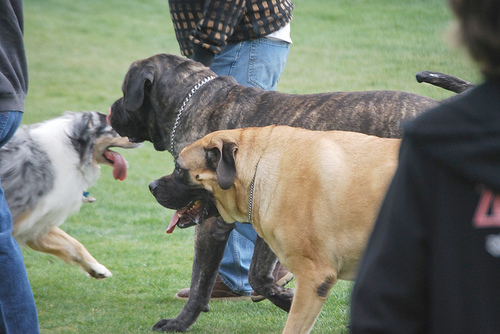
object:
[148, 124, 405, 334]
dog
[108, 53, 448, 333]
dog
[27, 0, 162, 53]
grass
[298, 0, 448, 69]
grass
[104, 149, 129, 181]
tounge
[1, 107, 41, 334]
jeans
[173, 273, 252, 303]
shoe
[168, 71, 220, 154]
chain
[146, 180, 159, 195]
nose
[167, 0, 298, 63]
sweater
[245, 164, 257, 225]
chain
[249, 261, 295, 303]
shoe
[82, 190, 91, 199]
tag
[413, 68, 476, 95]
tail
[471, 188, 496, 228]
letter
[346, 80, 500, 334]
hoodie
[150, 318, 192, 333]
paw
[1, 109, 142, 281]
dog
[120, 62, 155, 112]
ear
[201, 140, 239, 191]
ear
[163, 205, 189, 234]
tounge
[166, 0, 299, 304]
man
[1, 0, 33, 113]
sweater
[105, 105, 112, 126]
tounge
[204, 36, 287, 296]
jeans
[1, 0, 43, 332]
people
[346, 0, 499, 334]
people